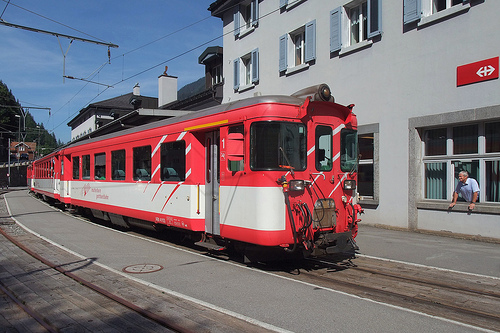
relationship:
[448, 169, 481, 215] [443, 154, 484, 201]
man hanging out window